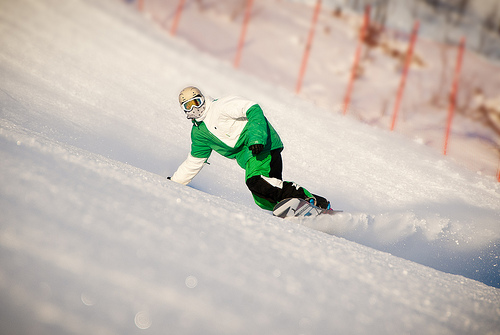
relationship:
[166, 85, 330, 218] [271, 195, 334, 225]
man on snowboard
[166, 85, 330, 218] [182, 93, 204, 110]
man wearing goggles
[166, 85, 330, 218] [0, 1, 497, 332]
man touching snow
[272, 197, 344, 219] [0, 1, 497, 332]
snowboard on snow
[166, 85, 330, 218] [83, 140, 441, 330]
man on snow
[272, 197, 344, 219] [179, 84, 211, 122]
snowboard wearing helmet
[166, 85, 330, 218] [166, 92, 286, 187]
man wearing jacket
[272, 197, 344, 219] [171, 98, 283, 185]
snowboard wearing jacket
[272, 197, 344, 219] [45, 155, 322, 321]
snowboard going down hill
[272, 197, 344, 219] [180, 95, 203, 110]
snowboard wearing goggles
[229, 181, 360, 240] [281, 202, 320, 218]
snowboard has writing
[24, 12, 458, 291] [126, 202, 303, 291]
mountains covered in snow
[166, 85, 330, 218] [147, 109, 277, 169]
man wearing jacket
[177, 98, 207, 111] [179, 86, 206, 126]
goggles on face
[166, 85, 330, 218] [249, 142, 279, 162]
man has hand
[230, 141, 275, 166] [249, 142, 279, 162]
glove on hand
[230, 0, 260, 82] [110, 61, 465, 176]
pole on side of ice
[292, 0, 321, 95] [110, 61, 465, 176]
pole on side of ice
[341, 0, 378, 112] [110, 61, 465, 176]
pole on side of ice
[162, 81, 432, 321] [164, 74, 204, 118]
man with face gear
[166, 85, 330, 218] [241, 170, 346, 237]
man wearing pants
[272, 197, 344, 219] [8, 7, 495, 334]
snowboard on slope